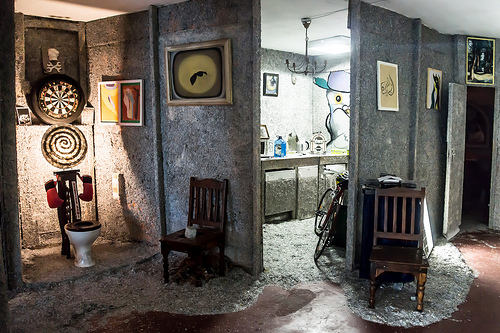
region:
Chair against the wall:
[154, 159, 231, 284]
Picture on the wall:
[157, 35, 233, 122]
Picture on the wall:
[89, 65, 154, 132]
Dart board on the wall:
[23, 67, 97, 127]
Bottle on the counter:
[269, 131, 294, 163]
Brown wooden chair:
[357, 173, 446, 313]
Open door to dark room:
[444, 79, 497, 231]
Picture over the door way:
[459, 32, 499, 87]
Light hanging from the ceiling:
[279, 11, 332, 81]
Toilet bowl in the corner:
[50, 211, 107, 269]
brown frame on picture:
[165, 41, 229, 117]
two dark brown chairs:
[136, 181, 450, 319]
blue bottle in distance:
[270, 134, 287, 161]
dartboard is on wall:
[33, 71, 80, 118]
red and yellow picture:
[90, 76, 157, 130]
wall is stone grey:
[158, 125, 225, 166]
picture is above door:
[452, 37, 494, 104]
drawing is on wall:
[320, 71, 355, 137]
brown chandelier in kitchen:
[287, 27, 334, 87]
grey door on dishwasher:
[257, 166, 304, 213]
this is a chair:
[145, 155, 253, 280]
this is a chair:
[361, 163, 448, 309]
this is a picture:
[367, 53, 416, 128]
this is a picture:
[419, 60, 449, 120]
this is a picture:
[461, 34, 498, 91]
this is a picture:
[164, 45, 236, 109]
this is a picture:
[91, 80, 118, 120]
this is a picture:
[116, 80, 146, 122]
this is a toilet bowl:
[54, 212, 109, 269]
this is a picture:
[259, 65, 292, 105]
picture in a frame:
[158, 43, 241, 115]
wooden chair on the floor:
[371, 180, 433, 307]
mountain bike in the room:
[302, 163, 347, 265]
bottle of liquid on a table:
[276, 131, 286, 158]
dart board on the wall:
[36, 71, 88, 126]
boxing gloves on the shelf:
[36, 170, 100, 207]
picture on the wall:
[422, 61, 451, 118]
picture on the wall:
[461, 31, 498, 88]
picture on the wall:
[263, 70, 283, 97]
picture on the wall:
[98, 70, 151, 130]